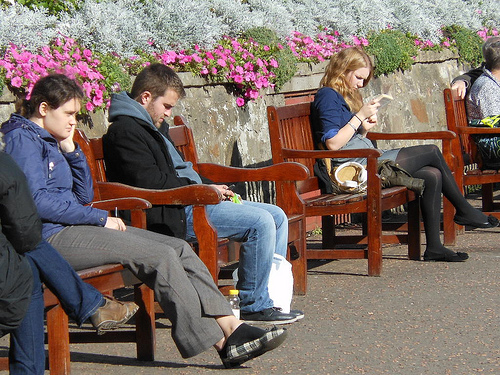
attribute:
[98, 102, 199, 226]
jacket — black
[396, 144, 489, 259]
tights — black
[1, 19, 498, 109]
flowers — pink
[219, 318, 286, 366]
shoes — black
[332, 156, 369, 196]
headphones — white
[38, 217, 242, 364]
pants — grey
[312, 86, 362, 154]
jacket — blue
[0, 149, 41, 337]
jacket — black